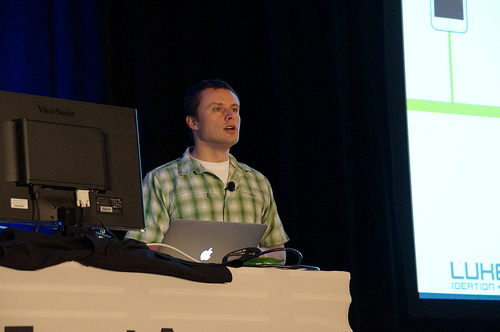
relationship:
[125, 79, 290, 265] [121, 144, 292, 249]
guy wearing shirt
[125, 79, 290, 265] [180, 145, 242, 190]
guy wearing shirt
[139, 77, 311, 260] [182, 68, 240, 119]
guy with hair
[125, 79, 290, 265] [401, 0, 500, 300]
guy doing a display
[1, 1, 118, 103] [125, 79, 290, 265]
drapes behind guy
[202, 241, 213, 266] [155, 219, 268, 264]
apple logo on back of computer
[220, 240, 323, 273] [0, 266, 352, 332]
cables on desk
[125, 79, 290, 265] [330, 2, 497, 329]
guy at computer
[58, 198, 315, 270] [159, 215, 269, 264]
cords on back of computer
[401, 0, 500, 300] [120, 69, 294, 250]
display next to man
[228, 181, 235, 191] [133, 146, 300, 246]
microphone on shirt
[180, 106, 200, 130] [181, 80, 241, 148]
ear on head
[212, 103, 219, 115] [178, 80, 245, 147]
eye on face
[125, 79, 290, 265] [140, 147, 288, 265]
guy wearing shirt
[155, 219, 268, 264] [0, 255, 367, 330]
computer on desk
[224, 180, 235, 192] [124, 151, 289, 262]
microphone on shirt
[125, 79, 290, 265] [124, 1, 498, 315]
guy gives presentation